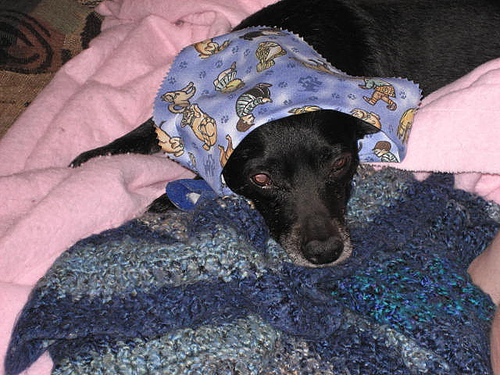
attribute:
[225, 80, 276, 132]
scarf — blue  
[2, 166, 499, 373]
blanket — crocheted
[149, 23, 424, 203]
scarf — blue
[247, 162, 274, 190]
eye — brown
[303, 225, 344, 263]
nose — black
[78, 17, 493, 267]
dog — black, laying down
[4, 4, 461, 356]
blanket — pink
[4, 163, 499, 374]
quilt — grey , blue 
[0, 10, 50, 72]
swirls — brown 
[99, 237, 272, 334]
dress — blue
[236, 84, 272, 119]
character — animated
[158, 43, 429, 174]
bib — blue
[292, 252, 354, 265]
mouth — white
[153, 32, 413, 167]
scarf — blue